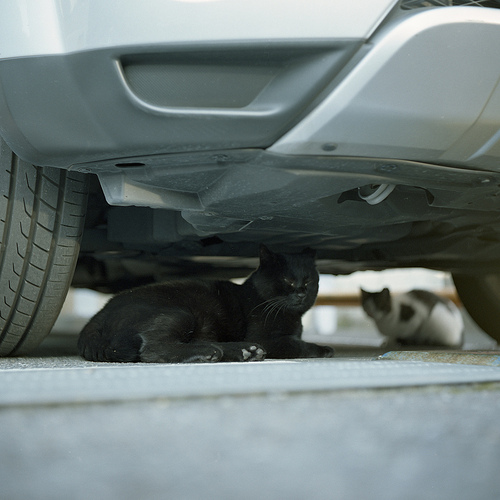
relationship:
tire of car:
[0, 139, 90, 357] [0, 1, 497, 368]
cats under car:
[77, 242, 334, 363] [97, 35, 393, 205]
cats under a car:
[77, 242, 334, 363] [0, 1, 497, 368]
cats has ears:
[77, 242, 334, 363] [248, 226, 325, 283]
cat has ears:
[360, 287, 465, 350] [342, 267, 396, 304]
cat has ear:
[360, 287, 465, 350] [358, 286, 370, 298]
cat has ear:
[360, 287, 465, 350] [380, 285, 392, 298]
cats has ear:
[77, 242, 334, 363] [253, 240, 273, 262]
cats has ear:
[77, 242, 334, 363] [297, 245, 321, 262]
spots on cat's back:
[400, 302, 416, 322] [390, 279, 485, 375]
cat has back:
[358, 285, 465, 350] [386, 277, 459, 364]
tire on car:
[0, 139, 90, 357] [0, 1, 497, 368]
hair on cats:
[73, 236, 390, 386] [77, 242, 334, 363]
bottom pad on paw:
[209, 330, 274, 403] [234, 338, 269, 361]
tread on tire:
[0, 138, 92, 357] [0, 139, 90, 357]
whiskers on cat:
[248, 296, 291, 331] [140, 231, 318, 361]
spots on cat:
[400, 302, 416, 322] [353, 250, 466, 390]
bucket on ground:
[315, 305, 345, 345] [313, 332, 350, 347]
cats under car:
[79, 245, 474, 373] [0, 1, 497, 368]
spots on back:
[393, 304, 420, 326] [392, 285, 471, 367]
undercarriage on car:
[113, 160, 482, 255] [5, 25, 496, 264]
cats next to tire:
[77, 242, 334, 363] [1, 150, 76, 356]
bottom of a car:
[119, 148, 496, 265] [0, 1, 497, 368]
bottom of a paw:
[233, 336, 274, 382] [239, 342, 266, 362]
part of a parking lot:
[43, 379, 491, 482] [98, 354, 450, 485]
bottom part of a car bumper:
[17, 31, 392, 187] [2, 11, 366, 158]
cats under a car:
[77, 242, 334, 363] [17, 14, 474, 374]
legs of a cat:
[144, 332, 336, 368] [66, 233, 343, 361]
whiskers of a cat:
[252, 293, 290, 325] [71, 241, 336, 360]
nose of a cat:
[287, 279, 315, 305] [71, 212, 350, 372]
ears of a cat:
[245, 232, 275, 265] [74, 220, 352, 420]